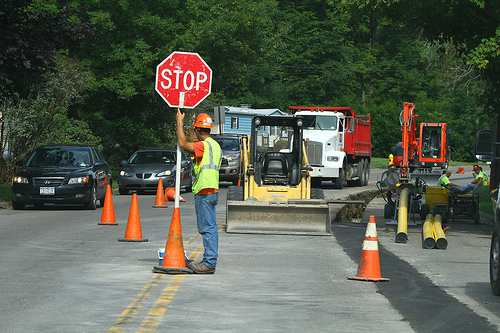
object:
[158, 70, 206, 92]
writing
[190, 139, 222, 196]
shirt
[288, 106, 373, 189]
dump truck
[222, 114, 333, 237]
bulldozer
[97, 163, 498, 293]
work site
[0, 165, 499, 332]
road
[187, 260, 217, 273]
boot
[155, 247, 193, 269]
water cooler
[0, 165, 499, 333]
ground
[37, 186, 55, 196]
license plate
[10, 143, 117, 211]
car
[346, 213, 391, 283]
safety cone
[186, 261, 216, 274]
shoe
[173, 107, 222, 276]
man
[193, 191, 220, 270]
pants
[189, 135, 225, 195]
safety vest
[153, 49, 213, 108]
stop sign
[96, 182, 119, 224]
traffic cone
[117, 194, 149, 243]
safety cone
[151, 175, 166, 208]
safety cone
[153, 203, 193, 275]
safety cone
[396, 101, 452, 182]
tractor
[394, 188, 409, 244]
pipes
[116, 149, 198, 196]
car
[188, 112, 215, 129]
helmet